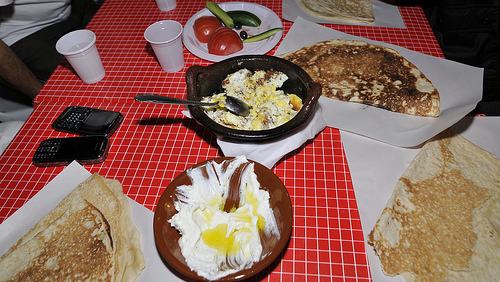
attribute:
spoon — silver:
[133, 90, 250, 117]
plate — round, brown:
[140, 146, 312, 280]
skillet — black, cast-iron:
[152, 44, 359, 172]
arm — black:
[1, 35, 51, 116]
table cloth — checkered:
[51, 0, 355, 268]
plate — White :
[184, 6, 289, 66]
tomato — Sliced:
[192, 10, 244, 57]